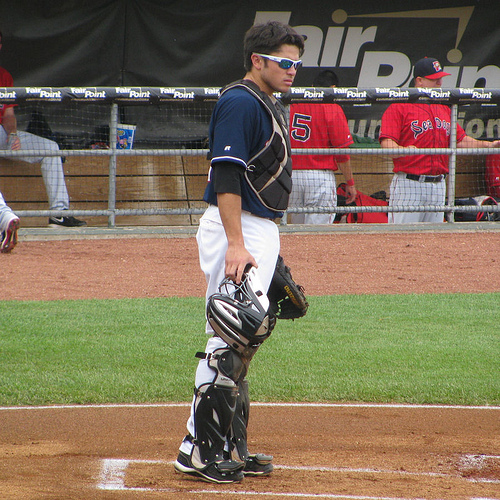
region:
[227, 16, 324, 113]
man wearing sun glasses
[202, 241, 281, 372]
silver and black helmet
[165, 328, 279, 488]
black and silver knee and shin pads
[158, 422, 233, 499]
black and white sneakers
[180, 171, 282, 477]
man wearing white pants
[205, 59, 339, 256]
man wearing blue shirt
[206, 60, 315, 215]
man wearing black vest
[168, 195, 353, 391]
man holding helmet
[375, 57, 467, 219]
man wearing red baseball shirt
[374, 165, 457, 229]
man wearing white pants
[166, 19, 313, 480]
Man with dark brown hair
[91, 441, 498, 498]
White lines in the dirt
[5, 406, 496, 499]
Red clay on baseball field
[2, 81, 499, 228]
Gray chain link fence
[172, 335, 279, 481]
Protective leg gear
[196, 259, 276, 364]
Black and silver helmet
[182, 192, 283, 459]
White baseball pants on man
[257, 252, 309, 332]
Black and yellow baseball glove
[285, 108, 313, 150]
Black number 5 on baseball jersey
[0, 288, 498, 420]
Green grass on baseball field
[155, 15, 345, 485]
the catcher on the field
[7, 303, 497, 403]
the grass on the field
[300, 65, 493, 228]
players in the dug out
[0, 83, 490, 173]
the railing of the dug out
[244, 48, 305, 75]
the catcher wearing sunglasses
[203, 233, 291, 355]
the catcher holding a helmet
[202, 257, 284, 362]
the helmet is silver and black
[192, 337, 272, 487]
the catcher wearing knee pads and shin guards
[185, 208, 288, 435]
the catcher wearing white pants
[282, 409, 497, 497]
dirt on the field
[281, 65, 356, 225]
player wearing red shirt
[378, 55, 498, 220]
player wearing red shirt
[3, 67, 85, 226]
player wearing red shirt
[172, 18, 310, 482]
player wearing blue shirt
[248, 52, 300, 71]
sunglasses with silver frame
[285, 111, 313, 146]
number on back of red jersey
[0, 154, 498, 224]
wooden bench in dugout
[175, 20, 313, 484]
baseball player wearing white pants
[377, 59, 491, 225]
baseball player wearing gray pants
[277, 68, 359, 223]
baseball player wearing gray pants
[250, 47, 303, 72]
suglasses with silver rim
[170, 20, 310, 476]
catcher standing on field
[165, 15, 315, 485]
catcher holding leather mitt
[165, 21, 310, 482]
catcher holding silver helmet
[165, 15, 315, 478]
catcher wearing white pants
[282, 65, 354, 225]
catcher wearing gray pants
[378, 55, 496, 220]
catcher wearing gray pants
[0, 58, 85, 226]
catcher wearing gray pants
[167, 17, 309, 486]
catcher wearing black vest